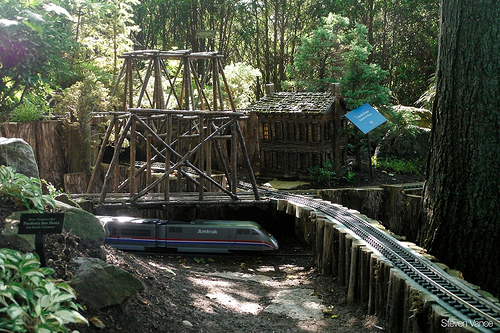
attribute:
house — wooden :
[235, 73, 367, 178]